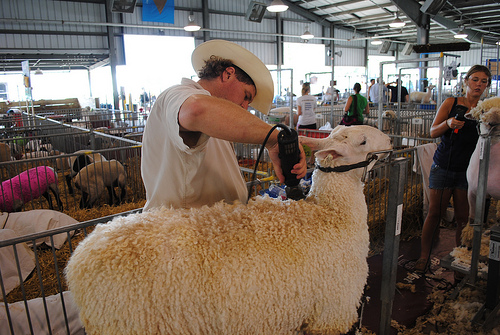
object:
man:
[138, 37, 310, 214]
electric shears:
[246, 123, 307, 205]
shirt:
[139, 76, 251, 214]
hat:
[191, 38, 275, 115]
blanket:
[0, 165, 57, 211]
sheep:
[0, 165, 65, 214]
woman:
[409, 63, 495, 276]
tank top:
[432, 96, 485, 173]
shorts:
[428, 160, 469, 190]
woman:
[339, 82, 371, 126]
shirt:
[348, 93, 368, 123]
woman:
[296, 82, 318, 130]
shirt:
[296, 94, 317, 126]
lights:
[182, 19, 203, 33]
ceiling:
[283, 0, 500, 46]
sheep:
[61, 123, 397, 334]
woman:
[384, 77, 409, 105]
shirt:
[386, 84, 408, 102]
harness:
[313, 153, 378, 173]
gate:
[94, 131, 146, 200]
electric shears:
[401, 104, 471, 291]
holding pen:
[1, 129, 277, 244]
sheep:
[449, 96, 500, 258]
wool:
[450, 242, 490, 269]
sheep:
[362, 109, 398, 134]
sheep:
[409, 84, 437, 104]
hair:
[194, 54, 256, 88]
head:
[296, 123, 394, 178]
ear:
[312, 148, 345, 162]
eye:
[359, 140, 367, 145]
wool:
[63, 165, 370, 335]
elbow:
[177, 96, 210, 131]